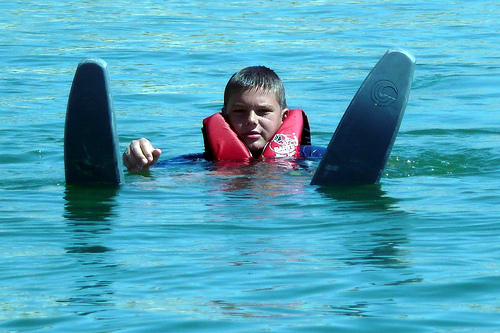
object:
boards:
[60, 54, 127, 189]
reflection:
[56, 190, 123, 316]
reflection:
[321, 193, 428, 291]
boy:
[119, 63, 328, 177]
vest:
[197, 102, 314, 169]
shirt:
[150, 134, 329, 172]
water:
[0, 0, 500, 48]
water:
[420, 58, 497, 163]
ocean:
[1, 0, 497, 333]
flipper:
[300, 42, 420, 198]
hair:
[218, 64, 288, 115]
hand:
[120, 137, 162, 175]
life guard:
[195, 108, 307, 170]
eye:
[256, 107, 274, 115]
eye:
[232, 109, 246, 114]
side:
[254, 101, 313, 174]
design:
[268, 128, 301, 162]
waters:
[0, 186, 500, 333]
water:
[0, 187, 500, 327]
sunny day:
[0, 0, 172, 58]